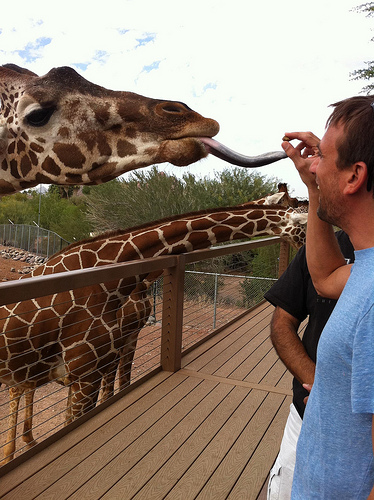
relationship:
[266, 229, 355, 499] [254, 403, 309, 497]
guy wearing pants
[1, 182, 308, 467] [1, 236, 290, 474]
giraffe behind fence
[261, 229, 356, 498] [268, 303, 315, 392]
guy has arm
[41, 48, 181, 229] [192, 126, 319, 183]
giraffe has tongue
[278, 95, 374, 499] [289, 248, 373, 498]
guy wearing blue shirt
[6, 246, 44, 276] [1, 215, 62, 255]
rocks near fence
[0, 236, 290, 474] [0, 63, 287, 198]
fence right of giraffe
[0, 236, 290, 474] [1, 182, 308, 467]
fence right of giraffe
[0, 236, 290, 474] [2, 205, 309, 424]
fence right of giraffe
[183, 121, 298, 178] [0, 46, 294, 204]
tongue of giraffe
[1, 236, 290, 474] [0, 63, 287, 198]
fence front of giraffe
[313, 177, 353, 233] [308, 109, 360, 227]
facial hair on face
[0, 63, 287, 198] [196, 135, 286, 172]
giraffe sticking out tongue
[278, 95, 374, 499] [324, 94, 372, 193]
guy has brown hair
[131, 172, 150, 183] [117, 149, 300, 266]
leaves on tree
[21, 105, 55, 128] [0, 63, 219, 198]
eye of giraffe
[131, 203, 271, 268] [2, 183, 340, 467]
neck of giraffe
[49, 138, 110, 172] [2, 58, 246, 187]
spots on giraffe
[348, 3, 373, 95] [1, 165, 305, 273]
leaves of tree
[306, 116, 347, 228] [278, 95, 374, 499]
face of guy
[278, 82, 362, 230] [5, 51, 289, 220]
guy smiling at a giraffe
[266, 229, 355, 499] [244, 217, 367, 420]
guy wears shirt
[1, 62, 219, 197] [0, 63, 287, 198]
head on giraffe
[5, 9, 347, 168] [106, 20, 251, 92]
clouds in sky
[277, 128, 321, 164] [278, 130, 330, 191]
fingers on hand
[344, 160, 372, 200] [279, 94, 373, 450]
ear on person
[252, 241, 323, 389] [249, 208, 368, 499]
arm on person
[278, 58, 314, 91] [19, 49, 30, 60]
white cloud in blue sky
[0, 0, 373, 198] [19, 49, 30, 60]
white cloud in blue sky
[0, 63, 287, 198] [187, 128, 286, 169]
giraffe reaching out tongue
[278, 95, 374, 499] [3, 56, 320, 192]
guy feeding giraffe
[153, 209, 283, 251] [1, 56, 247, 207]
spots on giraffe